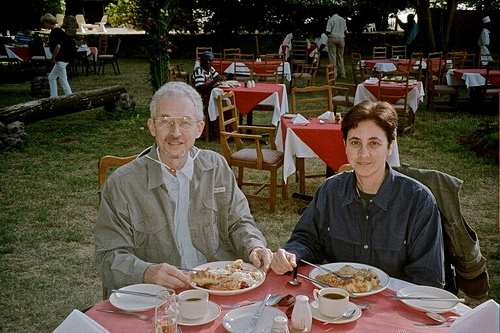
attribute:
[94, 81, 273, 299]
man — sitting, eating, outdoors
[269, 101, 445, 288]
lady — sitting, eating, outdoors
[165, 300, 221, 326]
saucer — white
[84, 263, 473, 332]
table — outdoors, set, red, white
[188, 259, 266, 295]
plate — white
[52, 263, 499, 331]
tablecloth — red, white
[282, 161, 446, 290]
shirt — dark blue, button down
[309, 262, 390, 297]
plate — white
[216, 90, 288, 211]
chair — wooden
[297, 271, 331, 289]
butterknife — stainless steel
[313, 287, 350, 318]
cup — white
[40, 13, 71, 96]
woman — walking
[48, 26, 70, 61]
shirt — black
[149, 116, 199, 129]
glasses — wire rimmed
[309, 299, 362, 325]
saucer — white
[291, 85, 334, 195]
chair — wooden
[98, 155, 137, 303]
chair — wooden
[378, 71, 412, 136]
chair — wooden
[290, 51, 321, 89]
chair — wooden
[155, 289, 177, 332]
glass — clear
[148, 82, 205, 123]
hair — white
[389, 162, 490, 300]
vest — green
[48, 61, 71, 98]
pants — white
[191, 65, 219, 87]
shirt — striped